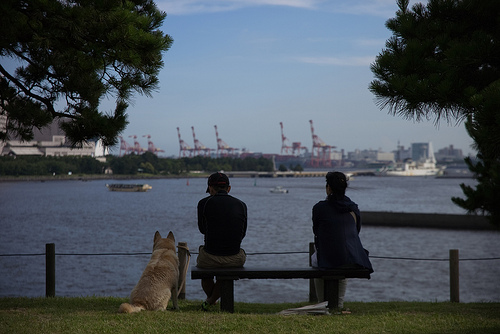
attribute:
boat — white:
[373, 143, 443, 176]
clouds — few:
[332, 52, 369, 86]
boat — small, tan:
[109, 180, 153, 194]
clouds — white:
[96, 2, 479, 160]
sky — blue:
[1, 1, 479, 154]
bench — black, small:
[195, 272, 371, 306]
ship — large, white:
[385, 150, 450, 179]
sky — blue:
[183, 55, 297, 106]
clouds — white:
[302, 55, 372, 67]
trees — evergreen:
[368, 0, 498, 216]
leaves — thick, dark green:
[0, 2, 173, 98]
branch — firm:
[0, 62, 105, 131]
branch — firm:
[0, 39, 107, 96]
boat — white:
[384, 161, 441, 176]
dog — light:
[115, 229, 184, 315]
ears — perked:
[148, 230, 177, 242]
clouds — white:
[221, 11, 351, 88]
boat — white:
[94, 169, 175, 206]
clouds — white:
[196, 23, 246, 48]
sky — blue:
[191, 12, 349, 127]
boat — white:
[432, 164, 479, 179]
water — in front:
[0, 173, 499, 301]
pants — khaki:
[198, 250, 247, 308]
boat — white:
[2, 96, 108, 163]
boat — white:
[361, 210, 497, 231]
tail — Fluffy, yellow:
[115, 288, 155, 312]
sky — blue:
[170, 27, 287, 75]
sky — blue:
[105, 9, 355, 130]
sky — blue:
[130, 11, 427, 143]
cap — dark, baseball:
[186, 154, 235, 201]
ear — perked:
[134, 209, 167, 251]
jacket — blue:
[295, 196, 399, 298]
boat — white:
[105, 177, 155, 198]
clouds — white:
[255, 43, 386, 79]